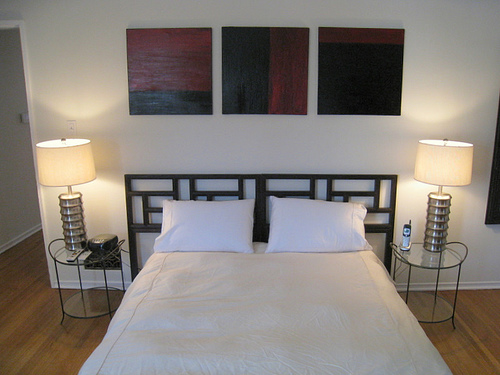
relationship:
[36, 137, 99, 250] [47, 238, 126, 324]
lamp on table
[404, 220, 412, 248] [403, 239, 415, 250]
phone on stand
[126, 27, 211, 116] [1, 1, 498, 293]
picture on wall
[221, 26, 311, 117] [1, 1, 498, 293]
picture on wall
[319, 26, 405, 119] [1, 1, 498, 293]
picture on wall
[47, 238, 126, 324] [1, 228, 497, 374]
table on floor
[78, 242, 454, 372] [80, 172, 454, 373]
sheet covering bed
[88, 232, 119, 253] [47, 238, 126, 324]
clock on table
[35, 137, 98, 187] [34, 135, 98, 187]
shade on lamp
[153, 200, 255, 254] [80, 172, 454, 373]
pillow on bed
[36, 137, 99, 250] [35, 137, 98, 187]
lamp has shade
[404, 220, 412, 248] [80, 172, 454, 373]
phone beside bed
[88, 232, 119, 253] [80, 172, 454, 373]
clock beside bed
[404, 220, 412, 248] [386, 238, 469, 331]
phone on table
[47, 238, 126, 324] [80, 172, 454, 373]
table beside bed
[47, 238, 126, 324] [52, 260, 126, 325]
table has legs